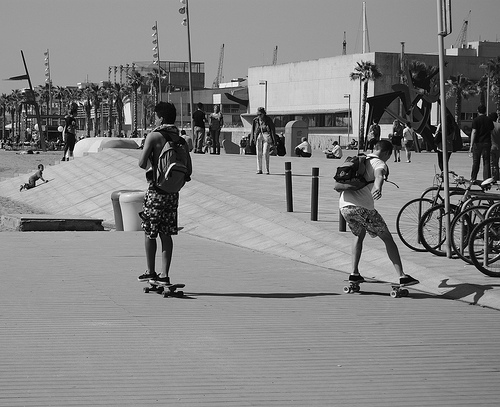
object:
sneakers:
[345, 271, 366, 283]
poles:
[283, 161, 293, 213]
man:
[137, 100, 192, 284]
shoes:
[148, 272, 170, 285]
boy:
[333, 139, 419, 287]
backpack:
[332, 152, 400, 193]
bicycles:
[395, 170, 499, 276]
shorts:
[137, 190, 180, 240]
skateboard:
[143, 280, 186, 300]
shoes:
[137, 271, 157, 282]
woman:
[249, 106, 275, 173]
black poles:
[309, 165, 320, 221]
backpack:
[149, 129, 192, 194]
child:
[20, 163, 47, 189]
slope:
[0, 148, 500, 311]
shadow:
[174, 292, 341, 299]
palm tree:
[347, 59, 382, 151]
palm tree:
[401, 59, 441, 123]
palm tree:
[445, 71, 478, 132]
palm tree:
[473, 56, 500, 121]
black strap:
[158, 128, 175, 143]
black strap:
[178, 135, 187, 145]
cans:
[110, 190, 144, 232]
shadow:
[395, 278, 500, 307]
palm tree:
[77, 87, 95, 138]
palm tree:
[86, 81, 106, 138]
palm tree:
[125, 70, 145, 137]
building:
[0, 40, 500, 137]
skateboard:
[342, 280, 410, 298]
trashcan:
[110, 188, 143, 234]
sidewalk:
[0, 149, 498, 407]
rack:
[396, 163, 500, 278]